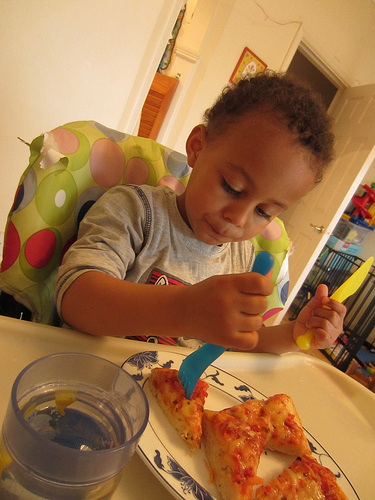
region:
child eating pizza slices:
[62, 73, 366, 347]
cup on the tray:
[10, 345, 155, 499]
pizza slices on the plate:
[155, 361, 334, 499]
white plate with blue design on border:
[125, 346, 338, 498]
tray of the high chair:
[1, 309, 371, 499]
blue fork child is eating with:
[178, 249, 272, 390]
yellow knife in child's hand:
[307, 253, 369, 350]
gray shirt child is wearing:
[68, 187, 266, 344]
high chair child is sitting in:
[3, 103, 373, 496]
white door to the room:
[287, 73, 373, 289]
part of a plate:
[322, 382, 337, 409]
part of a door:
[290, 276, 300, 283]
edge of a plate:
[155, 416, 171, 441]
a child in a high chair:
[68, 64, 279, 404]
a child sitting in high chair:
[54, 167, 321, 486]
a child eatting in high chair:
[63, 164, 369, 445]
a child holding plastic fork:
[73, 174, 347, 482]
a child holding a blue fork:
[97, 162, 374, 422]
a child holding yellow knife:
[159, 159, 372, 444]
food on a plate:
[122, 306, 330, 487]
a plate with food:
[99, 303, 327, 497]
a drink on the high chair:
[16, 324, 219, 487]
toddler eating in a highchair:
[56, 69, 348, 358]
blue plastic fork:
[182, 251, 270, 398]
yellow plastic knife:
[297, 256, 374, 353]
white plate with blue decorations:
[117, 349, 358, 499]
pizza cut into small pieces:
[152, 366, 340, 499]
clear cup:
[2, 351, 147, 498]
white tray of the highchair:
[0, 315, 372, 498]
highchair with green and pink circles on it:
[0, 121, 373, 499]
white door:
[258, 84, 373, 326]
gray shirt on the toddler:
[56, 183, 259, 346]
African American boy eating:
[84, 76, 337, 361]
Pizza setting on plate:
[107, 344, 336, 499]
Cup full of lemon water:
[1, 339, 162, 499]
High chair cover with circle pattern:
[12, 108, 269, 333]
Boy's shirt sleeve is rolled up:
[33, 182, 237, 354]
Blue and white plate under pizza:
[108, 328, 366, 499]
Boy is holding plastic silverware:
[183, 221, 373, 406]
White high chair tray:
[2, 313, 372, 499]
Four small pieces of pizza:
[160, 364, 340, 499]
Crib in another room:
[316, 220, 373, 364]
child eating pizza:
[59, 71, 367, 361]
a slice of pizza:
[271, 456, 308, 497]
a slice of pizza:
[211, 400, 248, 496]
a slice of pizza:
[238, 390, 309, 446]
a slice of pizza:
[135, 337, 211, 453]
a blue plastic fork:
[172, 270, 272, 411]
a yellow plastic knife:
[272, 238, 371, 364]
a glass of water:
[17, 319, 137, 488]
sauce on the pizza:
[152, 351, 205, 432]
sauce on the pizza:
[205, 431, 270, 491]